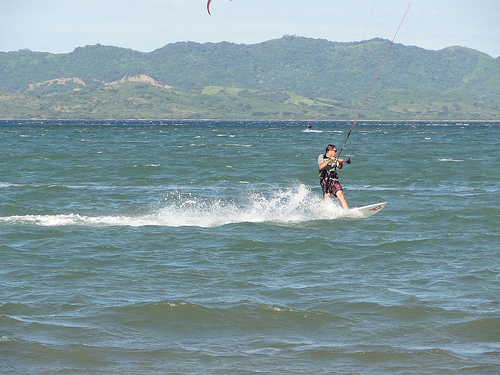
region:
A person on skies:
[291, 138, 394, 238]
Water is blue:
[79, 238, 348, 351]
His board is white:
[315, 198, 407, 233]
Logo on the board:
[361, 196, 398, 224]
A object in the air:
[194, 2, 239, 33]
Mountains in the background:
[0, 10, 498, 132]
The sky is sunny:
[48, 8, 168, 35]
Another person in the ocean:
[292, 120, 318, 135]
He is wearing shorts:
[316, 175, 352, 203]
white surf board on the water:
[328, 202, 390, 241]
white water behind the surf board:
[163, 194, 328, 230]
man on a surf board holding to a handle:
[302, 144, 347, 220]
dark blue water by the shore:
[419, 98, 488, 140]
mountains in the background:
[313, 40, 493, 122]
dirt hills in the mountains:
[42, 71, 158, 101]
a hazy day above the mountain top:
[246, 1, 351, 46]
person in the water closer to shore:
[281, 120, 321, 165]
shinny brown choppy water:
[82, 255, 237, 355]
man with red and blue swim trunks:
[301, 175, 346, 201]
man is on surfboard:
[325, 149, 370, 218]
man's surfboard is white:
[333, 193, 389, 227]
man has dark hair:
[315, 141, 345, 169]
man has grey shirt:
[318, 152, 345, 182]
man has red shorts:
[306, 176, 345, 198]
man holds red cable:
[346, 0, 426, 147]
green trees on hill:
[31, 41, 411, 113]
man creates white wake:
[144, 189, 316, 248]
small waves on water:
[90, 107, 345, 203]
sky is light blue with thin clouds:
[90, 5, 315, 52]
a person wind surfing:
[304, 120, 395, 234]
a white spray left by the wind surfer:
[147, 177, 311, 262]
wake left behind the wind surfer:
[89, 182, 277, 232]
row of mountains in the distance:
[62, 46, 347, 118]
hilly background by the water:
[54, 46, 274, 125]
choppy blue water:
[39, 133, 174, 178]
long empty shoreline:
[46, 106, 424, 134]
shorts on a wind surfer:
[322, 165, 346, 202]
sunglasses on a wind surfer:
[329, 146, 340, 156]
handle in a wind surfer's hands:
[322, 149, 353, 169]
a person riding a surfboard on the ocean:
[276, 124, 403, 243]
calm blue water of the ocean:
[221, 271, 432, 336]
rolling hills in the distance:
[43, 32, 438, 128]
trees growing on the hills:
[181, 39, 353, 93]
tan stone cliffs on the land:
[21, 72, 172, 89]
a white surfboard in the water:
[355, 196, 400, 223]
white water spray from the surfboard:
[150, 173, 321, 240]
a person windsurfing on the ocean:
[183, 0, 321, 133]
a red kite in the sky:
[193, 2, 230, 29]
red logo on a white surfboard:
[365, 205, 384, 212]